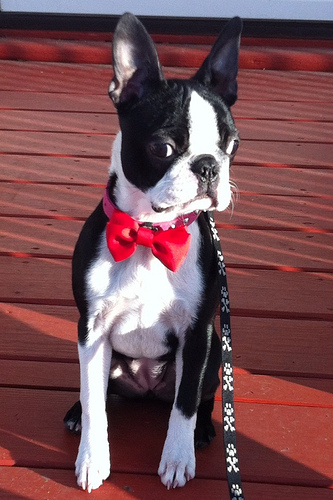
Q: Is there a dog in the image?
A: Yes, there is a dog.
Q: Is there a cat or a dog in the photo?
A: Yes, there is a dog.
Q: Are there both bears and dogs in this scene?
A: No, there is a dog but no bears.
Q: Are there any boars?
A: No, there are no boars.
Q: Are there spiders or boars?
A: No, there are no boars or spiders.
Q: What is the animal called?
A: The animal is a dog.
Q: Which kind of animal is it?
A: The animal is a dog.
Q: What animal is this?
A: This is a dog.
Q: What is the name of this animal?
A: This is a dog.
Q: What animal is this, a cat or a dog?
A: This is a dog.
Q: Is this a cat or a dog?
A: This is a dog.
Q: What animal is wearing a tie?
A: The dog is wearing a tie.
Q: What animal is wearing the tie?
A: The dog is wearing a tie.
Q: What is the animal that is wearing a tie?
A: The animal is a dog.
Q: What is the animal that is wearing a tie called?
A: The animal is a dog.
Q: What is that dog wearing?
A: The dog is wearing a tie.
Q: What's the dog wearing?
A: The dog is wearing a tie.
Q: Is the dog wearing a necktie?
A: Yes, the dog is wearing a necktie.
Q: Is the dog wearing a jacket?
A: No, the dog is wearing a necktie.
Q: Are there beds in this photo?
A: No, there are no beds.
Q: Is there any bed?
A: No, there are no beds.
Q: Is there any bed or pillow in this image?
A: No, there are no beds or pillows.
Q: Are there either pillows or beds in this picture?
A: No, there are no beds or pillows.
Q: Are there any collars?
A: Yes, there is a collar.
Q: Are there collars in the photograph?
A: Yes, there is a collar.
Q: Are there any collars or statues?
A: Yes, there is a collar.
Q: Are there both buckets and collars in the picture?
A: No, there is a collar but no buckets.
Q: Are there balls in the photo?
A: No, there are no balls.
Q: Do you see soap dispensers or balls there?
A: No, there are no balls or soap dispensers.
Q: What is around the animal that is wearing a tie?
A: The collar is around the dog.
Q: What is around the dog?
A: The collar is around the dog.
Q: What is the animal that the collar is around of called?
A: The animal is a dog.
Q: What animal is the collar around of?
A: The collar is around the dog.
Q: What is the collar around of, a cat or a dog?
A: The collar is around a dog.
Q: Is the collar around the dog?
A: Yes, the collar is around the dog.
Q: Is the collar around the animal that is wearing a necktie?
A: Yes, the collar is around the dog.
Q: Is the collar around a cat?
A: No, the collar is around the dog.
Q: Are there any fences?
A: No, there are no fences.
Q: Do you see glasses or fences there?
A: No, there are no fences or glasses.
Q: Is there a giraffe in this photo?
A: No, there are no giraffes.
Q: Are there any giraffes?
A: No, there are no giraffes.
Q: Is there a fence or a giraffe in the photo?
A: No, there are no giraffes or fences.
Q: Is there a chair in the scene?
A: No, there are no chairs.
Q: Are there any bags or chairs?
A: No, there are no chairs or bags.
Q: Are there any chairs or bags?
A: No, there are no chairs or bags.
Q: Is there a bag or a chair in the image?
A: No, there are no chairs or bags.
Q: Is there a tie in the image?
A: Yes, there is a tie.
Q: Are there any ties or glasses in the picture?
A: Yes, there is a tie.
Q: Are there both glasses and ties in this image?
A: No, there is a tie but no glasses.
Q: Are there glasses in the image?
A: No, there are no glasses.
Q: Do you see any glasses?
A: No, there are no glasses.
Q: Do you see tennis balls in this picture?
A: No, there are no tennis balls.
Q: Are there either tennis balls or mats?
A: No, there are no tennis balls or mats.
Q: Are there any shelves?
A: No, there are no shelves.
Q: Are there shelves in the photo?
A: No, there are no shelves.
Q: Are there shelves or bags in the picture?
A: No, there are no shelves or bags.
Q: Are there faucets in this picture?
A: No, there are no faucets.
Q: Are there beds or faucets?
A: No, there are no faucets or beds.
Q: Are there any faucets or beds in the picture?
A: No, there are no faucets or beds.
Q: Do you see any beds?
A: No, there are no beds.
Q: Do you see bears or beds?
A: No, there are no beds or bears.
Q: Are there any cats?
A: No, there are no cats.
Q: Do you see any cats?
A: No, there are no cats.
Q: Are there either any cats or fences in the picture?
A: No, there are no cats or fences.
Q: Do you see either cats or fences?
A: No, there are no cats or fences.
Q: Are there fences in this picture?
A: No, there are no fences.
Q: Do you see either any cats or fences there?
A: No, there are no fences or cats.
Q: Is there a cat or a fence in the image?
A: No, there are no fences or cats.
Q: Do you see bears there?
A: No, there are no bears.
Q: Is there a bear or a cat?
A: No, there are no bears or cats.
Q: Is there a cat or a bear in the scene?
A: No, there are no bears or cats.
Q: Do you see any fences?
A: No, there are no fences.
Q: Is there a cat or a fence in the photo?
A: No, there are no fences or cats.